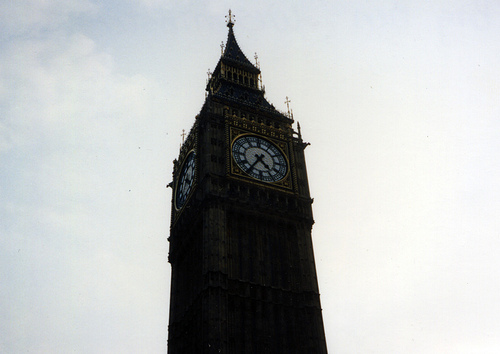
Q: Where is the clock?
A: Near the top of the tower.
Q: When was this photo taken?
A: During the daytime.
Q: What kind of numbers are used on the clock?
A: Roman Numerals.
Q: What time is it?
A: 4:35.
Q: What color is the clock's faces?
A: White.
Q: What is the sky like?
A: Mostly cloudy.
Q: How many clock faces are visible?
A: Two.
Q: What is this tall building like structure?
A: It's a tower.